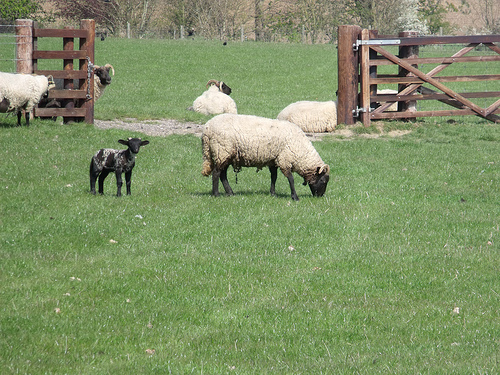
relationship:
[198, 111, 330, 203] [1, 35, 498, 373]
sheep eating grass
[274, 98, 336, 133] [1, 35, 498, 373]
sheep laying on grass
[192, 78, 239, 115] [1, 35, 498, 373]
sheep laying on grass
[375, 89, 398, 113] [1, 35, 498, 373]
sheep laying on grass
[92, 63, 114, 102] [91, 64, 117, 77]
sheep has horns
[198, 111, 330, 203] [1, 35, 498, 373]
sheep in grass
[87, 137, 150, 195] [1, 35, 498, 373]
sheep in grass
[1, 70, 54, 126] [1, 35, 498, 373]
sheep in grass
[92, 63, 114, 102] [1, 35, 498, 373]
sheep in grass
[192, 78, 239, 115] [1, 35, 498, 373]
sheep in grass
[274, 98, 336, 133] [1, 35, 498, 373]
sheep in grass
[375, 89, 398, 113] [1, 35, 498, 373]
sheep in grass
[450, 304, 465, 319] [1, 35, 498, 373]
flower in grass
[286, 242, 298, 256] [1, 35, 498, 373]
flower in grass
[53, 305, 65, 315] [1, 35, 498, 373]
flower in grass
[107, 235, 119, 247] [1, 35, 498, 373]
flower in grass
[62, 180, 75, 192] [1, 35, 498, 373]
flower in grass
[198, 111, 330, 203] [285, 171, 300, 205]
sheep has a leg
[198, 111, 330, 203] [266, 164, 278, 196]
sheep has a leg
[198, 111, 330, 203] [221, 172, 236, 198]
sheep has a leg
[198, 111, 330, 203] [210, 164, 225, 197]
sheep has a leg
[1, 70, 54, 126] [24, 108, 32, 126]
sheep has a leg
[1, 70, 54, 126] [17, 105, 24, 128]
sheep has a leg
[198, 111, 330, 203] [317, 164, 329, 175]
sheep has an ear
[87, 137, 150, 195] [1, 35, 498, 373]
sheep standing in grass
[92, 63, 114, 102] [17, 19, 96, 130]
sheep standing beside fence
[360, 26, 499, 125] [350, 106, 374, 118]
gate has a hinge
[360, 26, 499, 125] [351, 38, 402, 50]
gate has a hinge